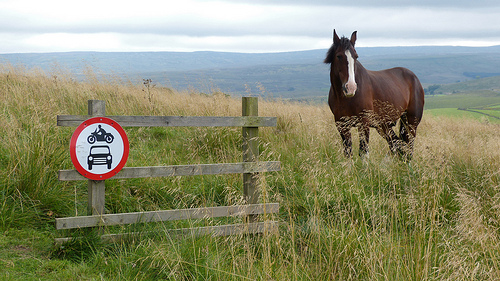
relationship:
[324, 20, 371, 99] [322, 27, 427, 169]
head of a horse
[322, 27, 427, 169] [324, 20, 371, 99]
horse with a head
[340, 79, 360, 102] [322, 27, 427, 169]
nose of a horse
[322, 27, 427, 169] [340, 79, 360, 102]
horse with a nose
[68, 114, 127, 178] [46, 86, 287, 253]
round sign on fence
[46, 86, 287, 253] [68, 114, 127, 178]
fence with round sign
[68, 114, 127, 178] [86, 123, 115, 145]
round sign with motorcycle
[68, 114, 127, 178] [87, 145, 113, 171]
round sign with car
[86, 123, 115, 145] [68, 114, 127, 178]
motorcycle on round sign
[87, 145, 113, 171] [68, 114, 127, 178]
car on round sign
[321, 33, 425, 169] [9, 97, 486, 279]
horse with grass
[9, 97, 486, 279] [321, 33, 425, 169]
grass under horse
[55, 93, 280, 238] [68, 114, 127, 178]
wooden fence with a round sign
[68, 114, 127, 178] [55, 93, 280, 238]
round sign with a wooden fence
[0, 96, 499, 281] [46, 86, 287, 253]
grass with a fence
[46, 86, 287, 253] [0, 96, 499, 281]
fence in grass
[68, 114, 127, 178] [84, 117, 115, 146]
round sign has a motorcycle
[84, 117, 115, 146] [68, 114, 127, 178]
motorcycle on round sign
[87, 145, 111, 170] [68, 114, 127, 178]
car with round sign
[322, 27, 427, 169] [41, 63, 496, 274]
horse standing in grass